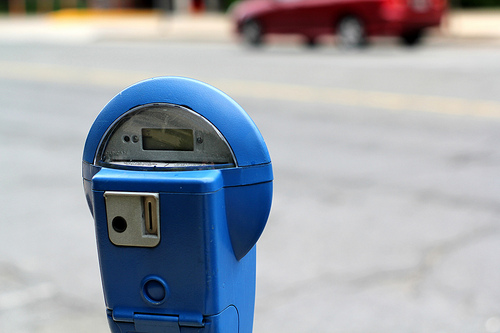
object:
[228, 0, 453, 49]
car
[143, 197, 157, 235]
coin slot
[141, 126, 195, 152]
meter screen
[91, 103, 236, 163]
glass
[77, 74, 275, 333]
parking meter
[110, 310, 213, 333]
hinges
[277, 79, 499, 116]
road line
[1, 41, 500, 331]
street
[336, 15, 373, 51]
tire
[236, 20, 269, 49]
tire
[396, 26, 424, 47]
tire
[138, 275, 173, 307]
round circle